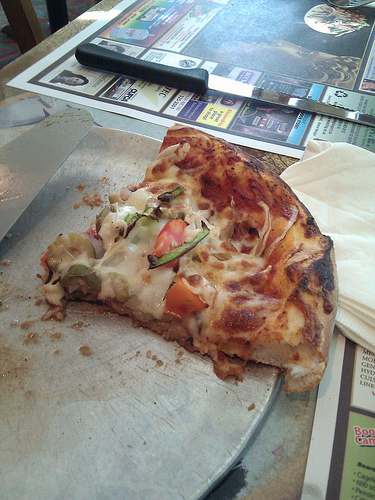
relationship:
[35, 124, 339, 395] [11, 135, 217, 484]
pizza on plate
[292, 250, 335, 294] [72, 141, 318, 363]
spot on pizza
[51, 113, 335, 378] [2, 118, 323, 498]
pizza on top of pan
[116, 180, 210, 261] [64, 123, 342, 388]
peppers are on top of pizza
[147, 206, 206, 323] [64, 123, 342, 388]
tomatoes are on top of pizza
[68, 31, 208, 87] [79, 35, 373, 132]
handle attached to knife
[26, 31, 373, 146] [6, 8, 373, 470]
newspaper on top of table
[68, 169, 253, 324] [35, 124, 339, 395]
cheese on top of pizza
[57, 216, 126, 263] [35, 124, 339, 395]
onions are on top of pizza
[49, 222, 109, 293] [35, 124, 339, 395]
olives are on top of pizza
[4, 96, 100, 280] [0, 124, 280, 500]
server on top of plate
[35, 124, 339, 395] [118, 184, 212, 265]
pizza has peppers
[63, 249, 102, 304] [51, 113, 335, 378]
mushroom on pizza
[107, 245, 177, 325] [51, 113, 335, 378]
cheese on pizza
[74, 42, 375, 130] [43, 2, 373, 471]
knife on table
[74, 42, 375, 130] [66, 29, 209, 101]
knife has handle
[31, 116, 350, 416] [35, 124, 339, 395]
slice of pizza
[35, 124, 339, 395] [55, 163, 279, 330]
pizza full of cheese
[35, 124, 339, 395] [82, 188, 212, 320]
pizza full of toppings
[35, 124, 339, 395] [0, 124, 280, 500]
pizza on plate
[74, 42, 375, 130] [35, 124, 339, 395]
knife next to pizza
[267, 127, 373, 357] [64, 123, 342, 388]
white napkins next to pizza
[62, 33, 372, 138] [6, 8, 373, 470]
knife on table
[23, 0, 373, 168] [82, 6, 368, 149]
placemat full of ads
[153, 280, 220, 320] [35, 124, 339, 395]
tomato slice on pizza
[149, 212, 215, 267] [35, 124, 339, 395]
green pepper on pizza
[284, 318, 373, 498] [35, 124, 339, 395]
placemat near pizza